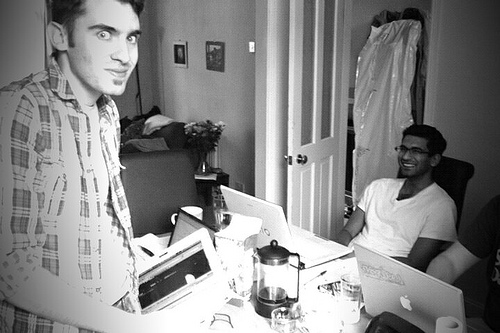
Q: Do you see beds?
A: Yes, there is a bed.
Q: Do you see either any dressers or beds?
A: Yes, there is a bed.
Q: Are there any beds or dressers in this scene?
A: Yes, there is a bed.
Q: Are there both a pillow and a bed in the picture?
A: No, there is a bed but no pillows.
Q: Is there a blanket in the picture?
A: No, there are no blankets.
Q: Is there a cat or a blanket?
A: No, there are no blankets or cats.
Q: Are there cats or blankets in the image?
A: No, there are no blankets or cats.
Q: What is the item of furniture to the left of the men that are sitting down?
A: The piece of furniture is a bed.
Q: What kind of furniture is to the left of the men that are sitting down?
A: The piece of furniture is a bed.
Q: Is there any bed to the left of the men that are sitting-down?
A: Yes, there is a bed to the left of the men.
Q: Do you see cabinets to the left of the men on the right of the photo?
A: No, there is a bed to the left of the men.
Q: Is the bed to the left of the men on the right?
A: Yes, the bed is to the left of the men.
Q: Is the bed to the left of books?
A: No, the bed is to the left of the men.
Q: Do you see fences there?
A: No, there are no fences.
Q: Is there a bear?
A: No, there are no bears.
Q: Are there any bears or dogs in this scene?
A: No, there are no bears or dogs.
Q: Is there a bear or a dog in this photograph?
A: No, there are no bears or dogs.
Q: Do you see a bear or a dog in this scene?
A: No, there are no bears or dogs.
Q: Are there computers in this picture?
A: Yes, there is a computer.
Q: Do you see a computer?
A: Yes, there is a computer.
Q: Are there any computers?
A: Yes, there is a computer.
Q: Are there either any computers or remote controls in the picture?
A: Yes, there is a computer.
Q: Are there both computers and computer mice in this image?
A: No, there is a computer but no computer mice.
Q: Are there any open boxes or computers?
A: Yes, there is an open computer.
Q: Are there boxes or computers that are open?
A: Yes, the computer is open.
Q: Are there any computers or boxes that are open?
A: Yes, the computer is open.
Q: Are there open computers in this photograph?
A: Yes, there is an open computer.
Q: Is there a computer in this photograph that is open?
A: Yes, there is a computer that is open.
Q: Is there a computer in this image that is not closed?
A: Yes, there is a open computer.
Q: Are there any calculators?
A: No, there are no calculators.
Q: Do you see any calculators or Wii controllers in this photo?
A: No, there are no calculators or Wii controllers.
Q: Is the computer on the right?
A: Yes, the computer is on the right of the image.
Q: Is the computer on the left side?
A: No, the computer is on the right of the image.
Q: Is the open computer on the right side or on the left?
A: The computer is on the right of the image.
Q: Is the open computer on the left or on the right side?
A: The computer is on the right of the image.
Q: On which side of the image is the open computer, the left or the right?
A: The computer is on the right of the image.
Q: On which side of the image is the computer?
A: The computer is on the right of the image.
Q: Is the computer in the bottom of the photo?
A: Yes, the computer is in the bottom of the image.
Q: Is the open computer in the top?
A: No, the computer is in the bottom of the image.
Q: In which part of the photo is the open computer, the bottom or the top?
A: The computer is in the bottom of the image.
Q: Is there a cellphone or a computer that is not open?
A: No, there is a computer but it is open.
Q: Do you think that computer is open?
A: Yes, the computer is open.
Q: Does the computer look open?
A: Yes, the computer is open.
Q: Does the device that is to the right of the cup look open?
A: Yes, the computer is open.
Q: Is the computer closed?
A: No, the computer is open.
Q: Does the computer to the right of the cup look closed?
A: No, the computer is open.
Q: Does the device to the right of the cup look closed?
A: No, the computer is open.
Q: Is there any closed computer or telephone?
A: No, there is a computer but it is open.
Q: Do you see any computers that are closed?
A: No, there is a computer but it is open.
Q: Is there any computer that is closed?
A: No, there is a computer but it is open.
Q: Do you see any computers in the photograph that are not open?
A: No, there is a computer but it is open.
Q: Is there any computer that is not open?
A: No, there is a computer but it is open.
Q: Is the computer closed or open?
A: The computer is open.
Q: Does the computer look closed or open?
A: The computer is open.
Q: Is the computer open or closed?
A: The computer is open.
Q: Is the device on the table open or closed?
A: The computer is open.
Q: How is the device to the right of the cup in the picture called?
A: The device is a computer.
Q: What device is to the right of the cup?
A: The device is a computer.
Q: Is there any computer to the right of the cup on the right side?
A: Yes, there is a computer to the right of the cup.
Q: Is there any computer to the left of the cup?
A: No, the computer is to the right of the cup.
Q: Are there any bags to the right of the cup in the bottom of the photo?
A: No, there is a computer to the right of the cup.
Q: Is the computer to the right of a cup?
A: Yes, the computer is to the right of a cup.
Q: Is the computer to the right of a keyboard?
A: No, the computer is to the right of a cup.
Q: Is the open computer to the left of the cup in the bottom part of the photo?
A: No, the computer is to the right of the cup.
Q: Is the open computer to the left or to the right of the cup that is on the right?
A: The computer is to the right of the cup.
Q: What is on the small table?
A: The computer is on the table.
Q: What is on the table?
A: The computer is on the table.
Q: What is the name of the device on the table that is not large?
A: The device is a computer.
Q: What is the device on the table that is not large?
A: The device is a computer.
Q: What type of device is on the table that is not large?
A: The device is a computer.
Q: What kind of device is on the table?
A: The device is a computer.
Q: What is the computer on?
A: The computer is on the table.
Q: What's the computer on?
A: The computer is on the table.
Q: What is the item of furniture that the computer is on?
A: The piece of furniture is a table.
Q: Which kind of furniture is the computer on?
A: The computer is on the table.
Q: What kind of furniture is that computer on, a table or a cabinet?
A: The computer is on a table.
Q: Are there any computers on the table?
A: Yes, there is a computer on the table.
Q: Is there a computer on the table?
A: Yes, there is a computer on the table.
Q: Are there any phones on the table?
A: No, there is a computer on the table.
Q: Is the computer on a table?
A: Yes, the computer is on a table.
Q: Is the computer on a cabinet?
A: No, the computer is on a table.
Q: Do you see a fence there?
A: No, there are no fences.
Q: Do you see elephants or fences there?
A: No, there are no fences or elephants.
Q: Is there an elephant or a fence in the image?
A: No, there are no fences or elephants.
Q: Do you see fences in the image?
A: No, there are no fences.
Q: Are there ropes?
A: No, there are no ropes.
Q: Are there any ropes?
A: No, there are no ropes.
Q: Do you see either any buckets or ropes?
A: No, there are no ropes or buckets.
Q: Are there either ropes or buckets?
A: No, there are no ropes or buckets.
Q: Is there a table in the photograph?
A: Yes, there is a table.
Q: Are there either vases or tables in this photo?
A: Yes, there is a table.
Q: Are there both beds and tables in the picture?
A: Yes, there are both a table and a bed.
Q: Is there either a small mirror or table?
A: Yes, there is a small table.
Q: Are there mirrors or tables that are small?
A: Yes, the table is small.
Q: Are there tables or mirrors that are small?
A: Yes, the table is small.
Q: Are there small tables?
A: Yes, there is a small table.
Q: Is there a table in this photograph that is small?
A: Yes, there is a table that is small.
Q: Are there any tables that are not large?
A: Yes, there is a small table.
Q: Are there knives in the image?
A: No, there are no knives.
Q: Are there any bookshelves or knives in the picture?
A: No, there are no knives or bookshelves.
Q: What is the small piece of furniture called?
A: The piece of furniture is a table.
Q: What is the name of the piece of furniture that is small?
A: The piece of furniture is a table.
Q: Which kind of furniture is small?
A: The furniture is a table.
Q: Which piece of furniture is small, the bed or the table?
A: The table is small.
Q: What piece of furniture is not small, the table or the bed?
A: The bed is not small.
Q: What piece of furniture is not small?
A: The piece of furniture is a bed.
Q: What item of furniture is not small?
A: The piece of furniture is a bed.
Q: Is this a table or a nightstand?
A: This is a table.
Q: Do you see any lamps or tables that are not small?
A: No, there is a table but it is small.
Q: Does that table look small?
A: Yes, the table is small.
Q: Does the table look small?
A: Yes, the table is small.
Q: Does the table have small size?
A: Yes, the table is small.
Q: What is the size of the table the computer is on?
A: The table is small.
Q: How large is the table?
A: The table is small.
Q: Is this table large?
A: No, the table is small.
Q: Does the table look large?
A: No, the table is small.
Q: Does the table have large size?
A: No, the table is small.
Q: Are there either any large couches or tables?
A: No, there is a table but it is small.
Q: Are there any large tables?
A: No, there is a table but it is small.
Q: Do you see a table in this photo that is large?
A: No, there is a table but it is small.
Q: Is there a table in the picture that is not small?
A: No, there is a table but it is small.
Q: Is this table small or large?
A: The table is small.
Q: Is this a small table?
A: Yes, this is a small table.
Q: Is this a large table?
A: No, this is a small table.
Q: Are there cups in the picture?
A: Yes, there is a cup.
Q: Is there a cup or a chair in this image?
A: Yes, there is a cup.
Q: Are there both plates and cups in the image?
A: No, there is a cup but no plates.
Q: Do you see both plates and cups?
A: No, there is a cup but no plates.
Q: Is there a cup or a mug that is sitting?
A: Yes, the cup is sitting.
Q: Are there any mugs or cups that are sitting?
A: Yes, the cup is sitting.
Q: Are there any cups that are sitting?
A: Yes, there is a cup that is sitting.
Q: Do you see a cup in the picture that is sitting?
A: Yes, there is a cup that is sitting.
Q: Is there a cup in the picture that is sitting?
A: Yes, there is a cup that is sitting.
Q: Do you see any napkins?
A: No, there are no napkins.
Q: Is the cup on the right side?
A: Yes, the cup is on the right of the image.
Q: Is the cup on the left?
A: No, the cup is on the right of the image.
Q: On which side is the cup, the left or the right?
A: The cup is on the right of the image.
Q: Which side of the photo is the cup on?
A: The cup is on the right of the image.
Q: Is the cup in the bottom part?
A: Yes, the cup is in the bottom of the image.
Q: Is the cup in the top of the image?
A: No, the cup is in the bottom of the image.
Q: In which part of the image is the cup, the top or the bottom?
A: The cup is in the bottom of the image.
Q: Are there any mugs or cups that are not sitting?
A: No, there is a cup but it is sitting.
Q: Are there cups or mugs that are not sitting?
A: No, there is a cup but it is sitting.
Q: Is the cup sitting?
A: Yes, the cup is sitting.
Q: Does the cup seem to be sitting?
A: Yes, the cup is sitting.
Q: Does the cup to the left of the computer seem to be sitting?
A: Yes, the cup is sitting.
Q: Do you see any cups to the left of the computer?
A: Yes, there is a cup to the left of the computer.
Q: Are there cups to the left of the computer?
A: Yes, there is a cup to the left of the computer.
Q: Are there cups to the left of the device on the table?
A: Yes, there is a cup to the left of the computer.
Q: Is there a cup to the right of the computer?
A: No, the cup is to the left of the computer.